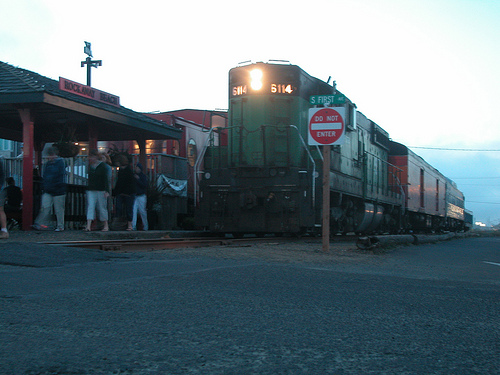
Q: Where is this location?
A: Station.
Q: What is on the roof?
A: Wind vale.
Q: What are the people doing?
A: Waiting to board.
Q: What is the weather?
A: Cloudy.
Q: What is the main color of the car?
A: Green.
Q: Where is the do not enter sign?
A: On the pole.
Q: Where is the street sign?
A: At the top of the pole.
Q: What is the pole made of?
A: Wood.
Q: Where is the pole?
A: Next to the tracks.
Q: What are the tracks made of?
A: Metal.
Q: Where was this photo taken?
A: At a train station.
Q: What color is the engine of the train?
A: Green.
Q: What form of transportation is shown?
A: A train.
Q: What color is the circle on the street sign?
A: Red.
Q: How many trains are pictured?
A: One.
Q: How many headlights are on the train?
A: Two.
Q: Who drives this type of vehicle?
A: An engineer.